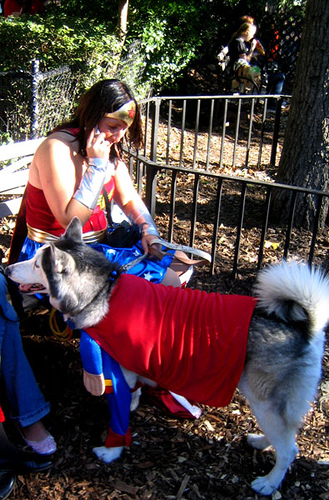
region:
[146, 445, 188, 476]
Group of sticks on the ground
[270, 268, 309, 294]
White tail of the dog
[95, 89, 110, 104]
Brunette hair of the woman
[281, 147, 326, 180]
Brown oak of the tree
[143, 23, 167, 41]
Green leaves on the bush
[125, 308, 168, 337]
Red superman cape of the dog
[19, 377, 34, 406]
Bottom section of a person's blue jeans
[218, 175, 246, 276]
Black fence surrounding tree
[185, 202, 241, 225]
Shadow of tree reflected by sunlight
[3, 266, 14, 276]
Black nose of dog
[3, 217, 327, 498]
Dog with superhero costume, and red cape.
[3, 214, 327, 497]
Black and white husky with costume on.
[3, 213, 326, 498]
Black and white dog with a curly tail.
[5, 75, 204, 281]
Woman in a superhero costume on.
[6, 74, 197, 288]
Woman in Wonder Woman costume on talking on phone.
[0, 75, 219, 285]
Woman with black hair sitting on a bench.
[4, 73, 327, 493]
Costumed woman holding dog leash.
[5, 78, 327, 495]
Woman in Wonder Woman costume with a dog in a Superman costume.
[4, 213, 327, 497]
Dog dressed as Superman.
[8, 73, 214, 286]
Woman on cell phone in Wonder Woman costume.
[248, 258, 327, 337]
a tail of a dog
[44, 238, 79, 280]
an ear of a dog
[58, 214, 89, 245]
an ear of a dog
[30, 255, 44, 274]
an eye of a dog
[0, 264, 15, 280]
the nose of a dog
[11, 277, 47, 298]
the mouth of a dog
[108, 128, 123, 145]
the nose of a woman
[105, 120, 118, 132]
the eye of a woman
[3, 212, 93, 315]
the head of a dog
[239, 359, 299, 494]
the hind leg of a dog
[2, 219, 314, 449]
Siberian Huskey in a costume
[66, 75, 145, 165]
Woman talking on phone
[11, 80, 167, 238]
Lady dressed as Wonder Woman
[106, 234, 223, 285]
Lady holding dog's leash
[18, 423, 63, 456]
Pink shoe on ground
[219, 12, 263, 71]
Kids standing in background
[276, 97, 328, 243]
Tree inside wrought iron fence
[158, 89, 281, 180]
Wrought iron fence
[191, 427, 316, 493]
Mulch dog is standing on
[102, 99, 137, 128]
Wonder Woman headband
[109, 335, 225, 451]
this is a dog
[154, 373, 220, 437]
this is a cape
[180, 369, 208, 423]
the cape is cloth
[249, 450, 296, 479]
this is a paw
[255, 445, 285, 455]
this is a leg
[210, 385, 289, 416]
the dog is light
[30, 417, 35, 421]
this is a woman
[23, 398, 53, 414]
this is a pair of jeans